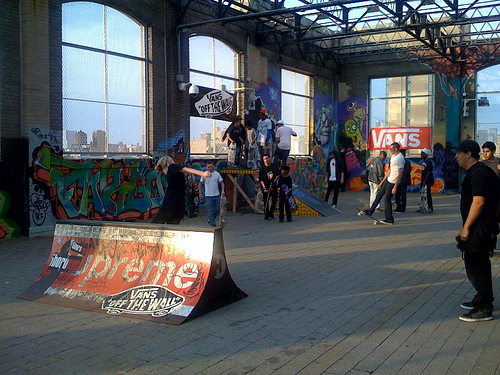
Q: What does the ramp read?
A: Supreme.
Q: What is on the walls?
A: Graffiti.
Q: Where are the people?
A: In the building.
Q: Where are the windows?
A: On the wall.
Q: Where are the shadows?
A: On the floor.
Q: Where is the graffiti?
A: On the walls.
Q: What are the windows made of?
A: Glass.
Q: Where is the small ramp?
A: On the floor.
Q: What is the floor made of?
A: Stone.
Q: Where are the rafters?
A: On the ceiling.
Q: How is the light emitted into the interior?
A: Windows and skylights.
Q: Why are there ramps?
A: Perform skateboard tricks.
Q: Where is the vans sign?
A: Rear window.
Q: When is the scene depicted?
A: Sunny day.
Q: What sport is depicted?
A: Skateboarding.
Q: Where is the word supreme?
A: Ramp.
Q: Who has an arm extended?
A: Skater behind ramp in foreground.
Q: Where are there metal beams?
A: Ceiling.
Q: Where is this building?
A: City.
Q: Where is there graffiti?
A: Walls.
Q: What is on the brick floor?
A: A red and white ramp.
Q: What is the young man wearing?
A: Black clothing and baseball cap.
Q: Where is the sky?
A: Above steel girders.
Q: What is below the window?
A: Blue, green and red graffiti.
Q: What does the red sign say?
A: Vans.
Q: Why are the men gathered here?
A: To skateboard.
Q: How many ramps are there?
A: Two.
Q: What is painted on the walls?
A: Graffiti.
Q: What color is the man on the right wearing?
A: Black.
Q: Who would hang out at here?
A: Skaters.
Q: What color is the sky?
A: Blue.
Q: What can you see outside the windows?
A: Buildings.